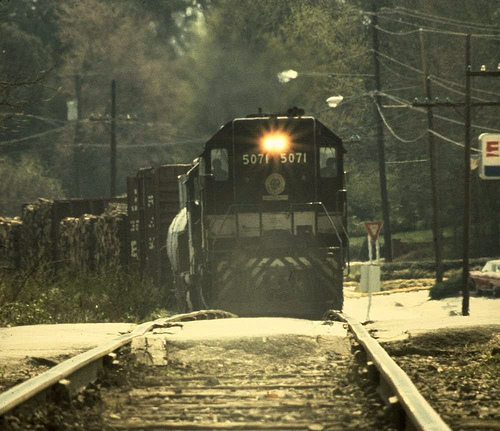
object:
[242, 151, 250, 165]
numbers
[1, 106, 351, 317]
train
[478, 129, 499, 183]
sign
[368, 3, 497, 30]
telephone wires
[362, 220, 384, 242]
sign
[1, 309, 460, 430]
tracks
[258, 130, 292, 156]
light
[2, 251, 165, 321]
grass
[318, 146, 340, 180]
window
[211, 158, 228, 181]
person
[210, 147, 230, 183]
window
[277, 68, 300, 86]
street light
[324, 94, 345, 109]
street light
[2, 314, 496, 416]
road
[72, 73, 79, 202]
utility pole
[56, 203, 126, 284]
cargo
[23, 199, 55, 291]
cargo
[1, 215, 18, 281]
cargo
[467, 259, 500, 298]
car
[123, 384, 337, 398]
plank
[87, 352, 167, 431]
gravel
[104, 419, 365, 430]
plank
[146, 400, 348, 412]
plank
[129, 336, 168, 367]
plank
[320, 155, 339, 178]
person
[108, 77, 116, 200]
pole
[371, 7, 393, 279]
pole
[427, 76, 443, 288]
pole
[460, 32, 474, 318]
pole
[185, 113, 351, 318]
locomotive engine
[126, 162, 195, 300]
box car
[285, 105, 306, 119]
horn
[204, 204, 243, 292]
ladder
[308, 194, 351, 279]
ladder